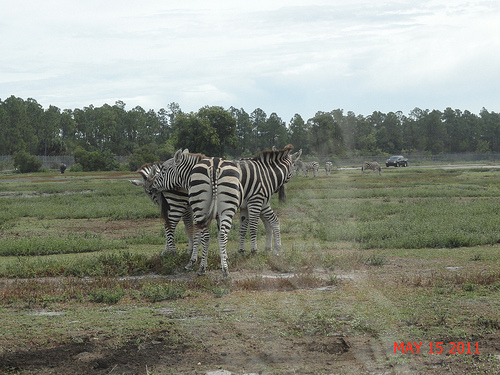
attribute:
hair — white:
[205, 201, 215, 230]